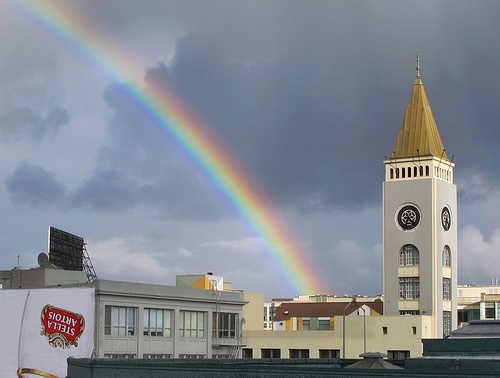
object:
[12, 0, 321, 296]
rainbow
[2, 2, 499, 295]
sky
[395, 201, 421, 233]
clock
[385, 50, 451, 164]
roof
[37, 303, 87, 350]
billboard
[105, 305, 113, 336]
windows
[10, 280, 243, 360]
building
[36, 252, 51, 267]
satellite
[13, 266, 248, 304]
roof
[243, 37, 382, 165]
clouds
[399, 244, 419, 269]
window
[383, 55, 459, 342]
church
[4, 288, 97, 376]
ad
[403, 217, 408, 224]
hands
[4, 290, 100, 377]
wall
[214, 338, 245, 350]
escape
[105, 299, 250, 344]
row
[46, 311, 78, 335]
stella artois